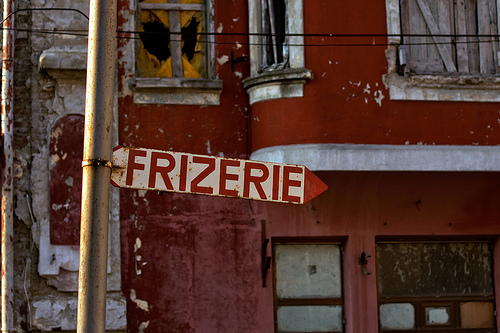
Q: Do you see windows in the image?
A: Yes, there is a window.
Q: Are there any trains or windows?
A: Yes, there is a window.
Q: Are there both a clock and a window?
A: No, there is a window but no clocks.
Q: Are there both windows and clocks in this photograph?
A: No, there is a window but no clocks.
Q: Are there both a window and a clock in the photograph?
A: No, there is a window but no clocks.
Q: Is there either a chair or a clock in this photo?
A: No, there are no chairs or clocks.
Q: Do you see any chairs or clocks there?
A: No, there are no chairs or clocks.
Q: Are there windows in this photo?
A: Yes, there is a window.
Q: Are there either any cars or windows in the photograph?
A: Yes, there is a window.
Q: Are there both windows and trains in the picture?
A: No, there is a window but no trains.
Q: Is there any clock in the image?
A: No, there are no clocks.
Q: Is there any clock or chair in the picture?
A: No, there are no clocks or chairs.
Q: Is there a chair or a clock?
A: No, there are no clocks or chairs.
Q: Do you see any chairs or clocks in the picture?
A: No, there are no clocks or chairs.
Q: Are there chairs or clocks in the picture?
A: No, there are no clocks or chairs.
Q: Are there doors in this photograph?
A: Yes, there is a door.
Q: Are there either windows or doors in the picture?
A: Yes, there is a door.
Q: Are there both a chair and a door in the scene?
A: No, there is a door but no chairs.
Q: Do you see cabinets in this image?
A: No, there are no cabinets.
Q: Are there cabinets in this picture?
A: No, there are no cabinets.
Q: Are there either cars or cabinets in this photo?
A: No, there are no cabinets or cars.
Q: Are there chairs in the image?
A: No, there are no chairs.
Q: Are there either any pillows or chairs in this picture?
A: No, there are no chairs or pillows.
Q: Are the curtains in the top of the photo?
A: Yes, the curtains are in the top of the image.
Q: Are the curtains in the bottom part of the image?
A: No, the curtains are in the top of the image.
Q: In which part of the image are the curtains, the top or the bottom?
A: The curtains are in the top of the image.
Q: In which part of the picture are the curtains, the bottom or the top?
A: The curtains are in the top of the image.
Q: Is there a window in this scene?
A: Yes, there is a window.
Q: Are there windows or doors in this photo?
A: Yes, there is a window.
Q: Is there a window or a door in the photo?
A: Yes, there is a window.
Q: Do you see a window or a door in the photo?
A: Yes, there is a window.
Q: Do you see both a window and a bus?
A: No, there is a window but no buses.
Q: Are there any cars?
A: No, there are no cars.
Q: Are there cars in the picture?
A: No, there are no cars.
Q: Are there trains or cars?
A: No, there are no cars or trains.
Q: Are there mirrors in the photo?
A: No, there are no mirrors.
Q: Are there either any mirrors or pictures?
A: No, there are no mirrors or pictures.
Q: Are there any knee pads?
A: No, there are no knee pads.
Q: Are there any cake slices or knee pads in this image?
A: No, there are no knee pads or cake slices.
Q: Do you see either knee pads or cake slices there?
A: No, there are no knee pads or cake slices.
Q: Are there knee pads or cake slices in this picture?
A: No, there are no knee pads or cake slices.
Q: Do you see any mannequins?
A: No, there are no mannequins.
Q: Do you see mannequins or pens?
A: No, there are no mannequins or pens.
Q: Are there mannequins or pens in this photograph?
A: No, there are no mannequins or pens.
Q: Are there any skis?
A: No, there are no skis.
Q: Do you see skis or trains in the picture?
A: No, there are no skis or trains.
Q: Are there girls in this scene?
A: No, there are no girls.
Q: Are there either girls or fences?
A: No, there are no girls or fences.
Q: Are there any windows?
A: Yes, there is a window.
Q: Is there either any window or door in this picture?
A: Yes, there is a window.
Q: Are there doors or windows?
A: Yes, there is a window.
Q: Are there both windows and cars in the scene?
A: No, there is a window but no cars.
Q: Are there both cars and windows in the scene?
A: No, there is a window but no cars.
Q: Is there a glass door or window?
A: Yes, there is a glass window.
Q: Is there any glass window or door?
A: Yes, there is a glass window.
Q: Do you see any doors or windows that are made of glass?
A: Yes, the window is made of glass.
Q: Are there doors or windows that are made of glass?
A: Yes, the window is made of glass.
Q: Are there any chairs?
A: No, there are no chairs.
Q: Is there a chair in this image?
A: No, there are no chairs.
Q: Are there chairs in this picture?
A: No, there are no chairs.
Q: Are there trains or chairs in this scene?
A: No, there are no chairs or trains.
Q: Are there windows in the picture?
A: Yes, there is a window.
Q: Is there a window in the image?
A: Yes, there is a window.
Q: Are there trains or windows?
A: Yes, there is a window.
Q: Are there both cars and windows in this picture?
A: No, there is a window but no cars.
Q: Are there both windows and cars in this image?
A: No, there is a window but no cars.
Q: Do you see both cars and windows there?
A: No, there is a window but no cars.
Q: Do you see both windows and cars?
A: No, there is a window but no cars.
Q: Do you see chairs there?
A: No, there are no chairs.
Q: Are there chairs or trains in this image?
A: No, there are no chairs or trains.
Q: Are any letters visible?
A: Yes, there are letters.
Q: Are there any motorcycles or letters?
A: Yes, there are letters.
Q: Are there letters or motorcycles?
A: Yes, there are letters.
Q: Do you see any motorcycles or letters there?
A: Yes, there are letters.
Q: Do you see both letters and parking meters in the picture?
A: No, there are letters but no parking meters.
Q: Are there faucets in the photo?
A: No, there are no faucets.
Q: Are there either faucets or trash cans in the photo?
A: No, there are no faucets or trash cans.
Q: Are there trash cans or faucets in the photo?
A: No, there are no faucets or trash cans.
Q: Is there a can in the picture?
A: No, there are no cans.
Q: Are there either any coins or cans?
A: No, there are no cans or coins.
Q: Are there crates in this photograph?
A: No, there are no crates.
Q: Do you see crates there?
A: No, there are no crates.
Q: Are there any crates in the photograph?
A: No, there are no crates.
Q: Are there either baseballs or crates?
A: No, there are no crates or baseballs.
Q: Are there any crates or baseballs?
A: No, there are no crates or baseballs.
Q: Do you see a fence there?
A: No, there are no fences.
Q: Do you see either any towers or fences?
A: No, there are no fences or towers.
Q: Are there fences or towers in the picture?
A: No, there are no fences or towers.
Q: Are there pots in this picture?
A: No, there are no pots.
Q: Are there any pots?
A: No, there are no pots.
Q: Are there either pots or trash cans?
A: No, there are no pots or trash cans.